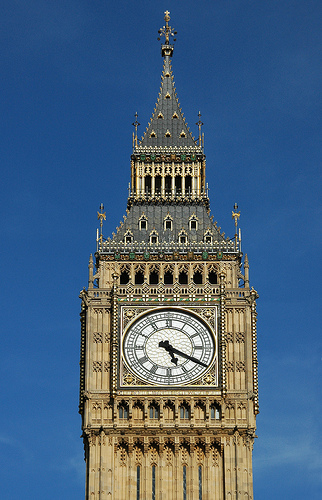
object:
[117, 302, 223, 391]
clock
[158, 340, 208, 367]
hands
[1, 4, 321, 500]
sky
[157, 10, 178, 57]
tip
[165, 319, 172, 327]
numeral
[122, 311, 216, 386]
face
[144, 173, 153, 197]
windows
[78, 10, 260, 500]
building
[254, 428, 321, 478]
cloud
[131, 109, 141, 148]
edge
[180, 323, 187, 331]
number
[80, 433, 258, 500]
bottom